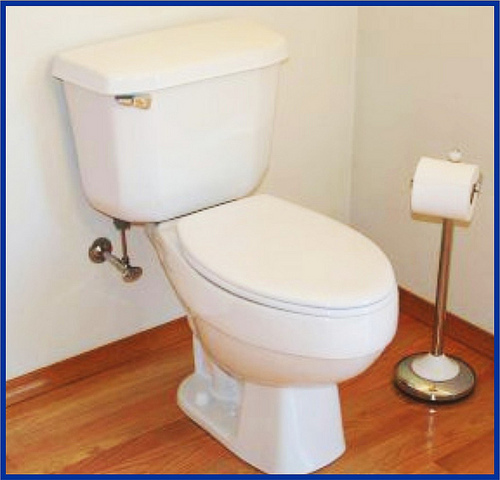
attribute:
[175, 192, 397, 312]
lid — down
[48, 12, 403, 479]
toilet — white, roll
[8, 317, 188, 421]
baseboard — wooden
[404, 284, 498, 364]
baseboard — wooden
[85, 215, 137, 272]
pipes — silver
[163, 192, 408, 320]
seat cover — white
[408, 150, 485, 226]
toilet paper — white